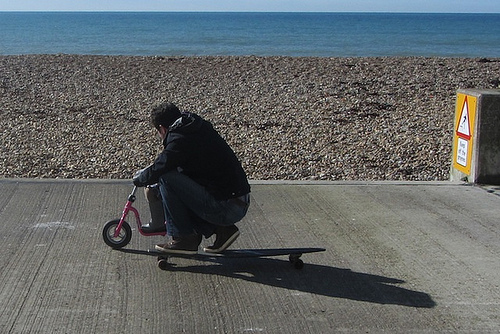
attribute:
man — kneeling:
[133, 103, 252, 254]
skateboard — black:
[144, 247, 325, 266]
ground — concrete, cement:
[1, 178, 499, 331]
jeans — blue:
[160, 172, 249, 238]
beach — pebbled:
[0, 54, 498, 183]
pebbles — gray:
[0, 55, 499, 182]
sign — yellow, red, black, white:
[449, 92, 476, 175]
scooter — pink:
[103, 180, 167, 248]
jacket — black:
[132, 115, 250, 195]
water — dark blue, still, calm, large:
[2, 12, 498, 58]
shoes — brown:
[156, 226, 237, 253]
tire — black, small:
[103, 219, 132, 251]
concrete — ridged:
[1, 178, 499, 332]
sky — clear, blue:
[1, 2, 499, 14]